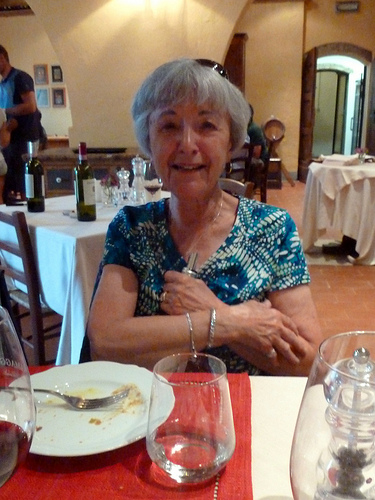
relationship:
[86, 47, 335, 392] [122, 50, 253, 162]
woman has hair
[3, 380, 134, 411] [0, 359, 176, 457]
fork on plate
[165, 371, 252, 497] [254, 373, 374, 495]
place mat on table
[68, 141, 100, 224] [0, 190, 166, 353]
bottle on table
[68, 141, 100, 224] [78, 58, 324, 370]
bottle behind woman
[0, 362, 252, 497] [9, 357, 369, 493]
place mat on table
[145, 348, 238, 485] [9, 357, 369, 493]
cup on table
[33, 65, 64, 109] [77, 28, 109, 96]
pictures on wall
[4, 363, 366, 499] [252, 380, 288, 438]
glass on tabled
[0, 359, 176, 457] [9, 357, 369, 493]
plate on table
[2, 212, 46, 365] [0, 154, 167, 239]
chair at table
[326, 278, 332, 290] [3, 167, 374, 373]
light reflecting off of floor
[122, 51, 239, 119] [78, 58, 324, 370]
gray hair on woman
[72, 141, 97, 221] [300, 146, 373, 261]
bottle on table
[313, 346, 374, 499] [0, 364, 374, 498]
pepper cracker on table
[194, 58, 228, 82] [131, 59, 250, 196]
sunglasses on head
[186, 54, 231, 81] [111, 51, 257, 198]
sunglasses on head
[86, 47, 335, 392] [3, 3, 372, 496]
woman looks camera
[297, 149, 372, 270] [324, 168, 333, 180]
table seen part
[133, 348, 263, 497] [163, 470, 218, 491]
cup has bottom